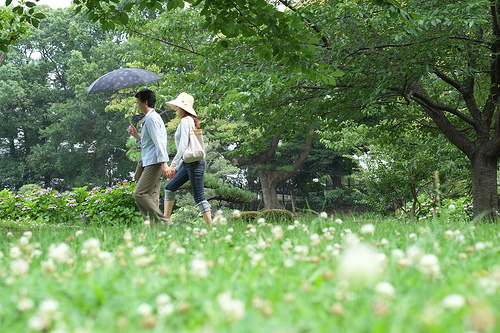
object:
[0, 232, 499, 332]
grass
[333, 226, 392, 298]
flowers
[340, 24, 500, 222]
tree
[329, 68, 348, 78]
leaves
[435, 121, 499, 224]
trunk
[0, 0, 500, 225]
background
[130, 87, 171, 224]
people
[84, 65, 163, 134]
umbrella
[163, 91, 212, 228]
woman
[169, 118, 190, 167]
arm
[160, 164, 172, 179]
hand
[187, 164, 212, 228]
leg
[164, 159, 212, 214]
jeans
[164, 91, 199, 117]
hat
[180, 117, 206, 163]
purse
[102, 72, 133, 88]
pattern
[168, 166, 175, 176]
hands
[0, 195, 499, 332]
field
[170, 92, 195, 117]
head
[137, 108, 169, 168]
jacket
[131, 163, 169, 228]
pants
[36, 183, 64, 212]
flowers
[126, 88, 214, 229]
couple